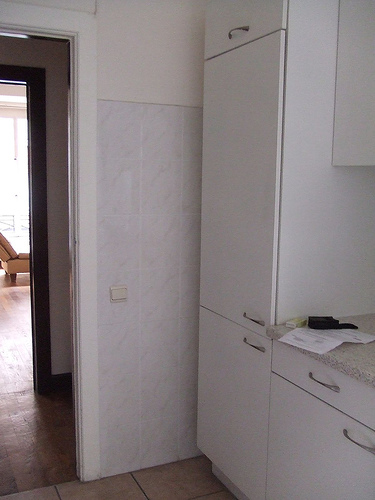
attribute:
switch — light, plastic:
[110, 281, 133, 305]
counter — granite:
[267, 312, 374, 390]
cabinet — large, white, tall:
[197, 30, 287, 337]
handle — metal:
[243, 308, 269, 332]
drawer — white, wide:
[270, 338, 374, 431]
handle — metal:
[308, 369, 339, 397]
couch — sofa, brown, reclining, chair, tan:
[0, 235, 33, 284]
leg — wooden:
[10, 270, 18, 283]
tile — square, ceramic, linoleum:
[136, 457, 229, 499]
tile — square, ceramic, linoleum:
[57, 469, 150, 498]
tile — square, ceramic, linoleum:
[0, 484, 59, 496]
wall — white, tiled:
[96, 100, 203, 481]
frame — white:
[68, 32, 101, 482]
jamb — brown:
[23, 82, 53, 398]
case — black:
[308, 312, 359, 333]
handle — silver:
[226, 24, 255, 38]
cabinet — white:
[203, 0, 285, 61]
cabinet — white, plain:
[195, 306, 275, 494]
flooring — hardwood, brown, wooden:
[2, 272, 33, 395]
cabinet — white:
[263, 375, 373, 498]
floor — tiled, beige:
[2, 459, 235, 498]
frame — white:
[1, 1, 98, 40]